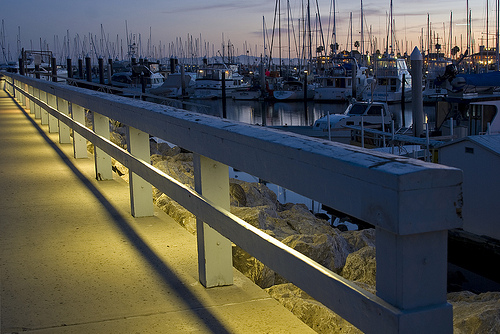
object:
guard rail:
[0, 69, 465, 333]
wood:
[243, 136, 315, 167]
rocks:
[242, 232, 354, 287]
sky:
[0, 0, 497, 58]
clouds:
[250, 7, 385, 40]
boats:
[360, 48, 428, 104]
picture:
[0, 4, 498, 333]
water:
[173, 88, 498, 295]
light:
[236, 104, 255, 124]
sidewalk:
[0, 79, 312, 334]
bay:
[0, 56, 499, 298]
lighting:
[3, 75, 15, 92]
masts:
[257, 16, 268, 64]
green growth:
[243, 281, 342, 333]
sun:
[426, 11, 495, 45]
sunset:
[302, 11, 497, 57]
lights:
[319, 60, 327, 67]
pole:
[216, 69, 226, 120]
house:
[425, 130, 499, 250]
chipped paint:
[366, 157, 397, 171]